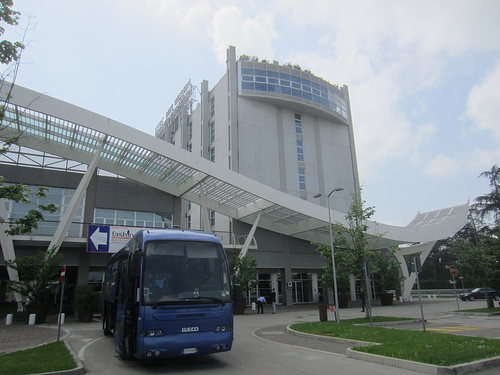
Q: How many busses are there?
A: One.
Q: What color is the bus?
A: Blue.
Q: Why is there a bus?
A: Transport people.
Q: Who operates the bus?
A: Driver.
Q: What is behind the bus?
A: Building.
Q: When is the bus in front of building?
A: Daytime.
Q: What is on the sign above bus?
A: Arrow.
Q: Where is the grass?
A: Ground.